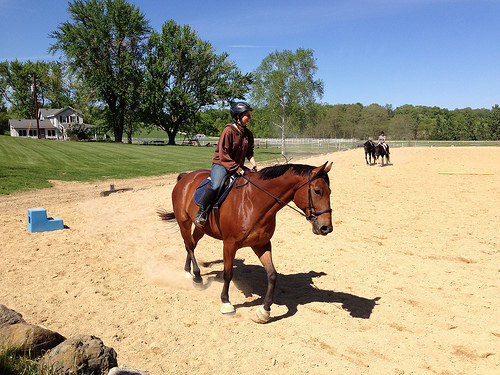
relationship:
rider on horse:
[194, 102, 272, 223] [172, 180, 334, 288]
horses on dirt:
[360, 138, 399, 173] [363, 170, 446, 201]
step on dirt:
[19, 198, 51, 238] [37, 245, 87, 271]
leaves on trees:
[97, 44, 176, 111] [67, 37, 176, 132]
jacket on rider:
[210, 114, 255, 174] [206, 111, 259, 207]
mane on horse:
[256, 163, 318, 180] [156, 158, 335, 324]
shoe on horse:
[247, 302, 273, 325] [156, 158, 335, 324]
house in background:
[7, 102, 97, 140] [0, 2, 499, 142]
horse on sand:
[156, 158, 335, 324] [152, 262, 352, 342]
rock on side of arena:
[34, 331, 119, 372] [0, 146, 499, 374]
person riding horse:
[192, 99, 260, 228] [156, 158, 335, 324]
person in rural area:
[192, 99, 260, 228] [3, 1, 499, 372]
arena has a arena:
[1, 142, 498, 372] [0, 146, 499, 374]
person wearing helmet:
[192, 99, 260, 228] [224, 96, 255, 118]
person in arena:
[374, 131, 389, 155] [1, 142, 498, 372]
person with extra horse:
[374, 131, 389, 155] [362, 137, 390, 166]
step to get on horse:
[27, 205, 48, 220] [156, 158, 335, 324]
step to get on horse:
[47, 213, 66, 230] [156, 158, 335, 324]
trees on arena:
[71, 51, 248, 143] [0, 146, 499, 374]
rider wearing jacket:
[194, 102, 259, 225] [210, 121, 255, 174]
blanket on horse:
[191, 178, 231, 207] [156, 158, 335, 324]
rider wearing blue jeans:
[194, 102, 259, 225] [210, 164, 228, 188]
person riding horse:
[374, 125, 386, 157] [372, 141, 392, 169]